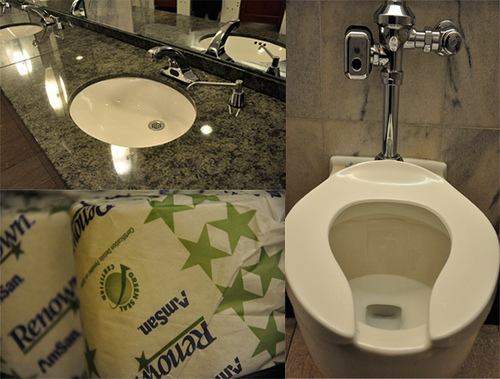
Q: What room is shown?
A: Bathroom.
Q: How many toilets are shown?
A: One.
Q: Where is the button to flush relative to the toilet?
A: Above.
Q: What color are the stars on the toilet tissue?
A: Green.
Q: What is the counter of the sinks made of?
A: Granite.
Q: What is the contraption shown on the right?
A: A toilet.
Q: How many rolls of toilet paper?
A: Two.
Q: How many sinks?
A: Two.